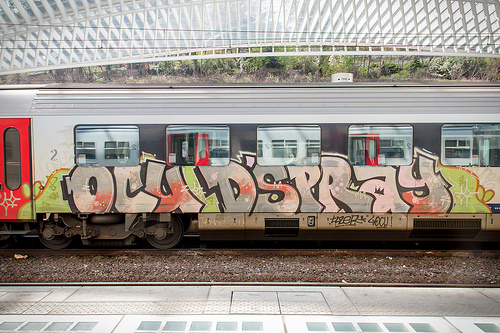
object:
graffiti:
[1, 147, 500, 223]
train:
[0, 82, 500, 250]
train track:
[0, 248, 495, 255]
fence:
[0, 0, 499, 74]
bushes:
[398, 61, 492, 78]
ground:
[3, 281, 499, 315]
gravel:
[92, 254, 173, 276]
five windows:
[73, 123, 499, 168]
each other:
[78, 144, 488, 150]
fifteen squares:
[3, 314, 499, 332]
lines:
[107, 316, 128, 333]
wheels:
[34, 214, 185, 250]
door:
[0, 118, 34, 220]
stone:
[136, 320, 262, 331]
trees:
[187, 21, 273, 80]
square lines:
[0, 23, 497, 50]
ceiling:
[0, 0, 500, 75]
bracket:
[198, 212, 498, 241]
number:
[50, 149, 59, 161]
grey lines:
[30, 89, 500, 116]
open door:
[166, 132, 210, 166]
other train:
[72, 124, 495, 166]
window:
[270, 139, 299, 158]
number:
[263, 143, 270, 150]